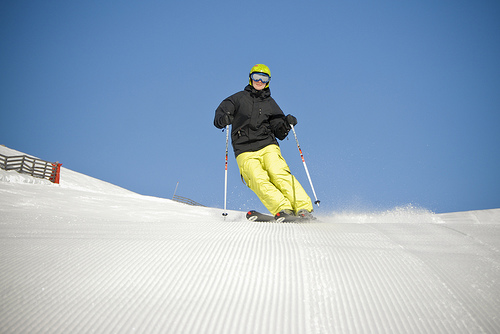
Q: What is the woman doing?
A: Skiing.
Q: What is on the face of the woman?
A: Goggles.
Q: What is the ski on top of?
A: Snow.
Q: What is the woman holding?
A: Ski poles.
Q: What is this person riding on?
A: Snow.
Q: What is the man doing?
A: Skiing.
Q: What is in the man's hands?
A: Two poles.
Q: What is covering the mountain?
A: Snow.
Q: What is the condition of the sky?
A: Blue and cloudless.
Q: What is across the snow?
A: Thin lines.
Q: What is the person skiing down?
A: A snow slope.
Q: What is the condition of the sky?
A: Bright blue and cloudless.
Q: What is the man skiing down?
A: A snow slope.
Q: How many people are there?
A: One.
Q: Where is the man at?
A: Ski resort.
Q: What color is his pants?
A: Yellow.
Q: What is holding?
A: Ski sticks.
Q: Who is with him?
A: No one.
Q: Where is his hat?
A: On his head.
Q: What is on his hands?
A: Gloves.